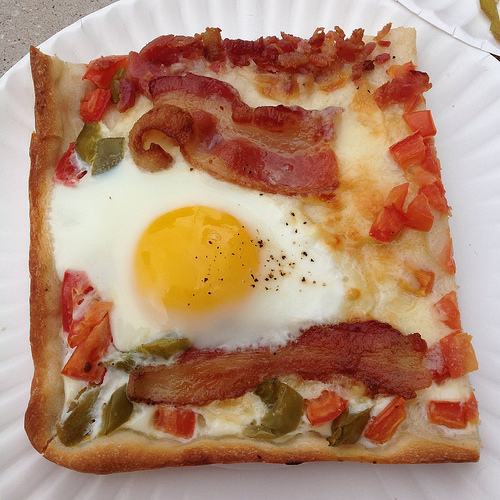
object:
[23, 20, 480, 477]
pizza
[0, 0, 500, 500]
dish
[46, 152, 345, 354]
egg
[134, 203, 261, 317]
yolk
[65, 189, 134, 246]
white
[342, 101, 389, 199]
cheese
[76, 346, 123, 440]
pepper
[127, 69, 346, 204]
bacon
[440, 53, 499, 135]
white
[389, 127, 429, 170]
tomato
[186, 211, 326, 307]
pepper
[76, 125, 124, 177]
jalapeno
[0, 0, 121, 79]
countertop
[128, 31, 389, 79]
bacon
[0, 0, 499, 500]
breakfast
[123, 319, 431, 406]
bacon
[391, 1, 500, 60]
paper plates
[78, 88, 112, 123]
vegetables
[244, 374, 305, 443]
green vegetable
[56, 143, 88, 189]
pepper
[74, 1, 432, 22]
fluted edges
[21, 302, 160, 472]
slice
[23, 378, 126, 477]
corner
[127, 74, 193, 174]
curled fat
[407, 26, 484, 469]
edges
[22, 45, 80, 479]
brown crust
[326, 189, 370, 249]
brown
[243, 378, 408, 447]
red and green pepper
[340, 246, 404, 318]
cheese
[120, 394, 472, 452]
peppers